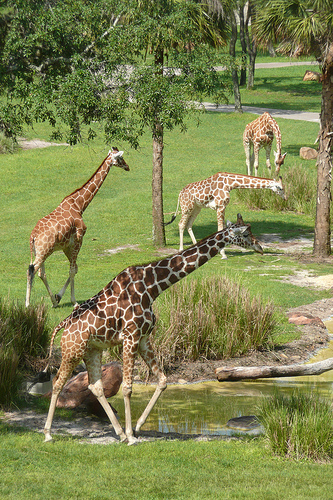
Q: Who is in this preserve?
A: Rothschild's giraffes.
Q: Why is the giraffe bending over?
A: To drink water.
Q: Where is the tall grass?
A: Around the pond and in a patch farther out.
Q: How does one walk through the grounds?
A: Grey pathway.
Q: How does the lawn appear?
A: Green and well maintained.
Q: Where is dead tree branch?
A: Along side the pond.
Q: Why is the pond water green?
A: Bacteria.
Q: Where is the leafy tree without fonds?
A: In the middle of the grass.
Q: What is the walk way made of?
A: Concrete.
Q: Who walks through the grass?
A: Giraffe.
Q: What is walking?
A: Giraffe walking next to creek.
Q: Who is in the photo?
A: Giraffe with its head straight out.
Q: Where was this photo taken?
A: Giraffe area zoo compound.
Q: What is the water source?
A: A pond.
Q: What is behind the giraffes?
A: Park dirt pedestrian walkway.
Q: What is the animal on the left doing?
A: Giraffe heading towards others.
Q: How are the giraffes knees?
A: Bent.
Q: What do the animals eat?
A: Green tree leaves giraffe food.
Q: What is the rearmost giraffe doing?
A: Grazing.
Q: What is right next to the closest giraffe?
A: Pond.